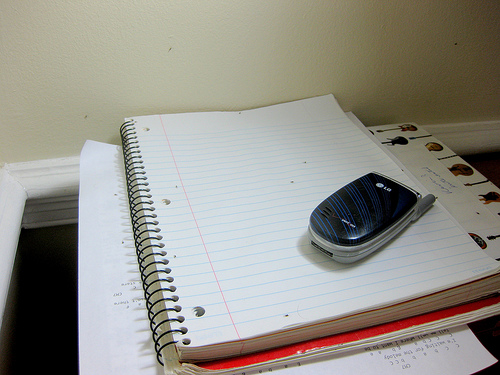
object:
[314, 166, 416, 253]
cellphone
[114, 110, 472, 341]
notebook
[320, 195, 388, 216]
cover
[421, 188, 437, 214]
antenna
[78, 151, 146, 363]
sheet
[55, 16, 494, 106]
wall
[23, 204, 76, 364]
surface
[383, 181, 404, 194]
lg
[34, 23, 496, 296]
picture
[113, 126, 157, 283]
spiral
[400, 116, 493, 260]
sticker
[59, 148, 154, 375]
paper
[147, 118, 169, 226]
holes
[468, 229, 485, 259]
man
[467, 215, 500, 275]
stamp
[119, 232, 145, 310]
words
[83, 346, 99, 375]
spot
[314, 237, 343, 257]
edge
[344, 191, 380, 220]
lines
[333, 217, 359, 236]
words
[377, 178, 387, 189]
circle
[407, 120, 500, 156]
edge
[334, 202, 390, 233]
stripes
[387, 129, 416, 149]
person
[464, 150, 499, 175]
floor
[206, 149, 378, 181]
lines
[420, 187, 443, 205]
tip